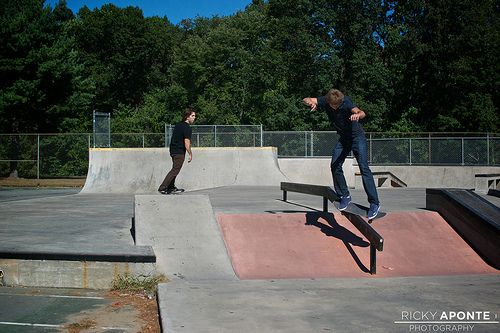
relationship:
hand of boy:
[350, 113, 360, 121] [300, 88, 382, 221]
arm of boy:
[349, 104, 367, 123] [300, 88, 382, 221]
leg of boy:
[352, 138, 382, 220] [300, 88, 382, 221]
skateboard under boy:
[332, 198, 384, 221] [300, 88, 382, 221]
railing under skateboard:
[280, 182, 382, 273] [335, 199, 385, 224]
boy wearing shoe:
[298, 86, 385, 226] [363, 198, 382, 220]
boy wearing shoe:
[298, 86, 385, 226] [335, 194, 352, 213]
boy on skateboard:
[300, 88, 382, 221] [332, 198, 384, 221]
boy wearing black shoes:
[156, 106, 198, 196] [156, 181, 183, 196]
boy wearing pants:
[157, 109, 199, 196] [158, 152, 184, 189]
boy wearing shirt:
[157, 109, 199, 196] [166, 121, 194, 153]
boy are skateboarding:
[300, 88, 382, 221] [159, 72, 386, 222]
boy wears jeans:
[298, 86, 385, 226] [321, 140, 381, 197]